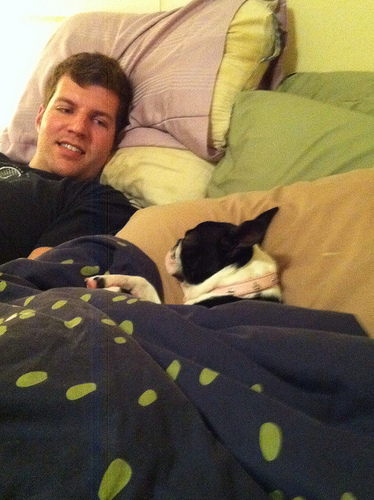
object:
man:
[4, 51, 136, 244]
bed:
[3, 292, 369, 497]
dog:
[134, 202, 291, 307]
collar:
[186, 277, 282, 297]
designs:
[10, 358, 51, 398]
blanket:
[13, 308, 361, 479]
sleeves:
[31, 187, 128, 247]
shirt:
[1, 163, 127, 245]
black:
[19, 189, 65, 211]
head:
[163, 219, 275, 292]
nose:
[164, 234, 184, 253]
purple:
[142, 8, 204, 113]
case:
[84, 10, 268, 126]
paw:
[85, 261, 166, 310]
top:
[77, 256, 161, 318]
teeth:
[58, 141, 84, 159]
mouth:
[54, 134, 92, 164]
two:
[288, 65, 361, 161]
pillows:
[226, 90, 372, 188]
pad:
[86, 278, 96, 288]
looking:
[45, 98, 121, 128]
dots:
[62, 374, 100, 407]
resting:
[124, 207, 299, 343]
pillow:
[140, 171, 366, 316]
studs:
[246, 278, 265, 296]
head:
[32, 47, 142, 172]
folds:
[183, 319, 314, 374]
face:
[169, 219, 211, 280]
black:
[190, 235, 221, 263]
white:
[166, 250, 183, 276]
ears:
[224, 193, 285, 256]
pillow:
[0, 0, 229, 155]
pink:
[85, 276, 99, 288]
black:
[95, 276, 106, 291]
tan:
[314, 204, 347, 263]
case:
[273, 180, 368, 310]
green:
[269, 111, 344, 166]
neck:
[179, 268, 298, 305]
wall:
[280, 0, 373, 73]